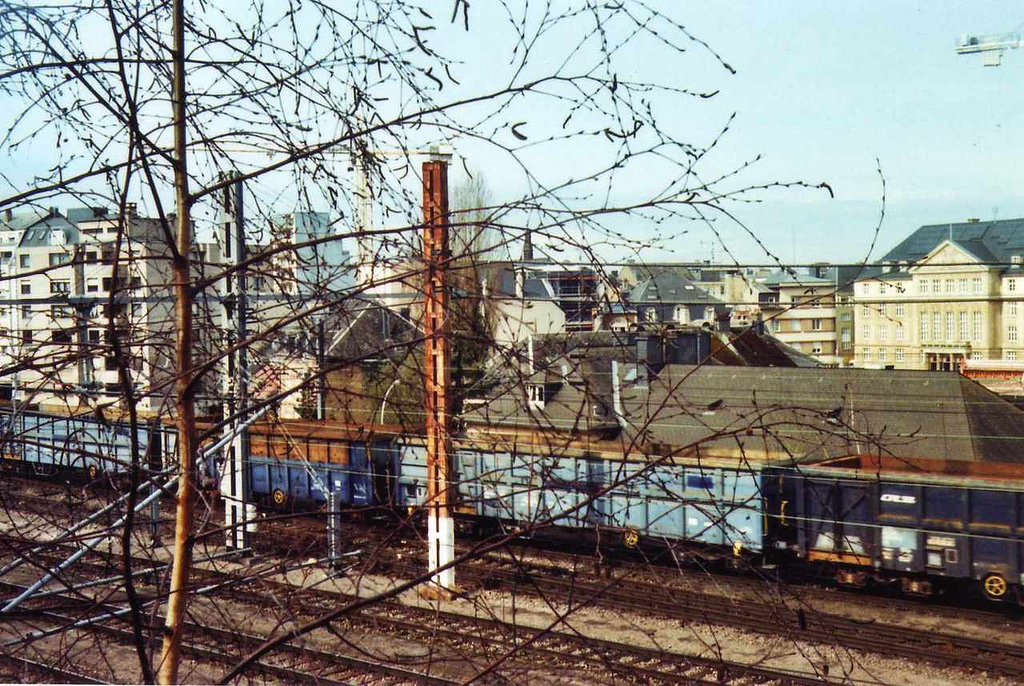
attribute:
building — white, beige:
[854, 218, 1022, 368]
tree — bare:
[3, 2, 821, 685]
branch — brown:
[187, 3, 741, 205]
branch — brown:
[214, 393, 926, 684]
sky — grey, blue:
[3, 4, 1021, 286]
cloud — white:
[68, 10, 877, 273]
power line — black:
[1, 258, 1023, 269]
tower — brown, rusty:
[421, 159, 460, 594]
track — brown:
[2, 534, 844, 685]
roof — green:
[855, 216, 1022, 281]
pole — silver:
[212, 171, 246, 556]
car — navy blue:
[793, 455, 1022, 574]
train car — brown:
[160, 416, 398, 516]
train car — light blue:
[397, 422, 797, 580]